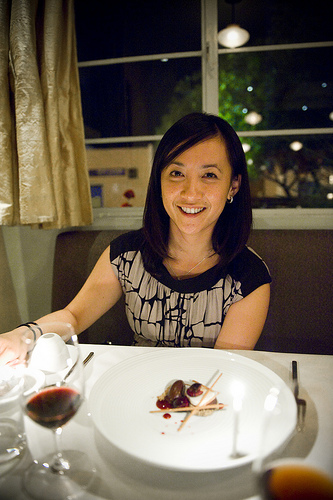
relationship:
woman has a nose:
[2, 111, 270, 351] [182, 177, 203, 202]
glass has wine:
[20, 321, 100, 499] [23, 387, 80, 427]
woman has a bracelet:
[2, 111, 270, 351] [24, 318, 46, 340]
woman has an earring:
[2, 111, 270, 351] [227, 197, 235, 204]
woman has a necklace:
[2, 111, 270, 351] [164, 242, 221, 263]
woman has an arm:
[2, 111, 270, 351] [215, 279, 267, 351]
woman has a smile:
[2, 111, 270, 351] [177, 205, 212, 217]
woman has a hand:
[2, 111, 270, 351] [2, 331, 30, 363]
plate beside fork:
[90, 347, 299, 473] [292, 361, 307, 427]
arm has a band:
[215, 279, 267, 351] [26, 321, 43, 343]